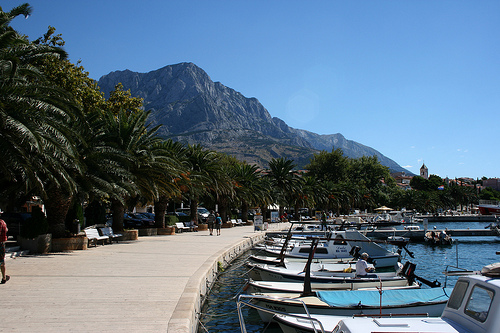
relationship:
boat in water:
[237, 238, 500, 332] [198, 220, 500, 332]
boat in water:
[249, 286, 454, 328] [198, 220, 500, 332]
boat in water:
[245, 261, 441, 296] [198, 220, 500, 332]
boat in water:
[245, 222, 377, 268] [198, 220, 500, 332]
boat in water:
[265, 229, 415, 267] [198, 220, 500, 332]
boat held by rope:
[237, 238, 500, 332] [194, 316, 210, 333]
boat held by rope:
[249, 286, 454, 328] [198, 298, 254, 317]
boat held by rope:
[245, 261, 441, 296] [200, 279, 248, 304]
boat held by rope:
[245, 222, 377, 268] [224, 255, 250, 266]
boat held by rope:
[265, 229, 415, 267] [228, 246, 267, 259]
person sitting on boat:
[356, 251, 377, 278] [246, 249, 403, 281]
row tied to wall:
[239, 219, 499, 332] [187, 222, 302, 333]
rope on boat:
[194, 316, 210, 333] [237, 238, 500, 332]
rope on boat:
[198, 298, 254, 317] [249, 286, 454, 328]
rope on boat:
[200, 279, 248, 304] [245, 261, 441, 296]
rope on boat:
[224, 255, 250, 266] [265, 229, 415, 267]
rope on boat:
[228, 246, 267, 259] [245, 222, 377, 268]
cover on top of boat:
[315, 287, 455, 308] [249, 286, 454, 328]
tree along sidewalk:
[0, 3, 87, 211] [0, 214, 483, 332]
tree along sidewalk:
[43, 109, 142, 238] [0, 214, 483, 332]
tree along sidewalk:
[145, 137, 195, 228] [0, 214, 483, 332]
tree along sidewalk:
[177, 144, 223, 225] [0, 214, 483, 332]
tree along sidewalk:
[261, 157, 306, 223] [0, 214, 483, 332]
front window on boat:
[463, 283, 495, 323] [237, 238, 500, 332]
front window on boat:
[446, 278, 469, 309] [237, 238, 500, 332]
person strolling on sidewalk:
[215, 212, 222, 236] [0, 214, 483, 332]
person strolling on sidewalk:
[206, 209, 216, 237] [0, 214, 483, 332]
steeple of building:
[420, 162, 429, 180] [394, 163, 445, 189]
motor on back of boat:
[397, 261, 441, 289] [245, 261, 441, 296]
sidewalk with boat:
[0, 214, 483, 332] [237, 238, 500, 332]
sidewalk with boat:
[0, 214, 483, 332] [249, 286, 454, 328]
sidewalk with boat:
[0, 214, 483, 332] [245, 261, 441, 296]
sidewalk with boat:
[0, 214, 483, 332] [246, 249, 403, 281]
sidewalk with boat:
[0, 214, 483, 332] [265, 229, 415, 267]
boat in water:
[246, 249, 403, 281] [198, 220, 500, 332]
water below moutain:
[198, 220, 500, 332] [94, 61, 420, 180]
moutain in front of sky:
[94, 61, 420, 180] [0, 0, 499, 181]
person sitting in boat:
[356, 251, 377, 278] [246, 249, 403, 281]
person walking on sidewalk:
[215, 212, 222, 236] [0, 214, 483, 332]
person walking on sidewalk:
[206, 209, 216, 237] [0, 214, 483, 332]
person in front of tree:
[215, 212, 222, 236] [261, 157, 306, 223]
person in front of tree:
[215, 212, 222, 236] [177, 144, 223, 225]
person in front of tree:
[206, 209, 216, 237] [145, 137, 195, 228]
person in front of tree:
[206, 209, 216, 237] [43, 109, 142, 238]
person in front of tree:
[206, 209, 216, 237] [0, 3, 87, 211]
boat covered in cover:
[249, 286, 454, 328] [315, 287, 455, 308]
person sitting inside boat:
[356, 251, 377, 278] [246, 249, 403, 281]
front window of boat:
[463, 283, 495, 323] [237, 238, 500, 332]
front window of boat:
[446, 278, 469, 309] [237, 238, 500, 332]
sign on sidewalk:
[253, 214, 263, 227] [0, 214, 483, 332]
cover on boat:
[315, 287, 455, 308] [249, 286, 454, 328]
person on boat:
[356, 251, 377, 278] [246, 249, 403, 281]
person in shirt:
[356, 251, 377, 278] [355, 259, 369, 276]